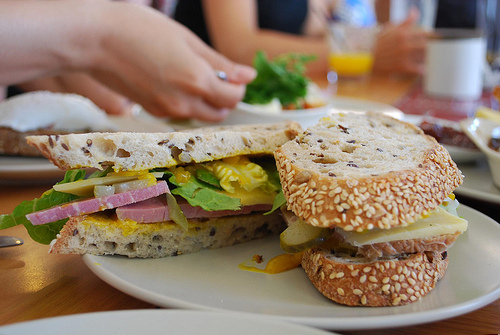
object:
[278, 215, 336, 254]
vegetables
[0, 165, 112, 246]
lettuce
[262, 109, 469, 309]
bread sandwich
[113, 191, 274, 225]
meat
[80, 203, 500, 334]
plate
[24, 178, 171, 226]
meat slice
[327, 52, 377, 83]
juice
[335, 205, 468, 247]
cheese slice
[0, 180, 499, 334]
table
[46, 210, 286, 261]
food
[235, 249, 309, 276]
cheese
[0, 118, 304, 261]
sandwich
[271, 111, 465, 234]
slice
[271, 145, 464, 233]
edge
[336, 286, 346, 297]
sesame seeds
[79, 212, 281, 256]
mustard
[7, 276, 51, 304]
part